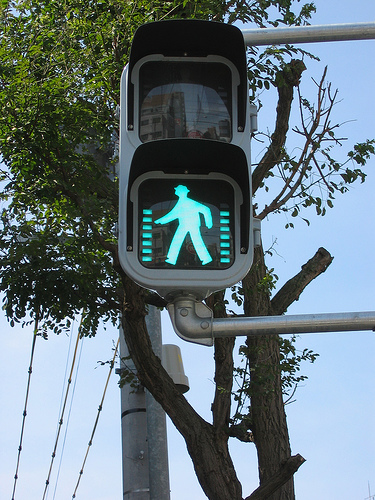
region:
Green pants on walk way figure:
[166, 231, 216, 274]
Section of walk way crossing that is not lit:
[125, 61, 247, 144]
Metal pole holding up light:
[179, 311, 367, 332]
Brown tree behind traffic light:
[142, 362, 304, 498]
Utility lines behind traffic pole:
[22, 357, 81, 480]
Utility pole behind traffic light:
[78, 324, 169, 498]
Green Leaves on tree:
[23, 184, 114, 316]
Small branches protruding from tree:
[276, 95, 371, 267]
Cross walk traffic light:
[90, 26, 273, 336]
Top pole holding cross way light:
[250, 19, 371, 63]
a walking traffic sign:
[124, 184, 232, 263]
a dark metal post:
[205, 318, 356, 341]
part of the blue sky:
[304, 378, 353, 473]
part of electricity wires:
[45, 363, 69, 433]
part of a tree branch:
[284, 87, 340, 202]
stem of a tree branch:
[262, 405, 287, 461]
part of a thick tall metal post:
[120, 417, 171, 494]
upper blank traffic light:
[150, 63, 215, 116]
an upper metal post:
[234, 20, 345, 47]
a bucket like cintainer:
[156, 339, 197, 393]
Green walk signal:
[113, 159, 273, 294]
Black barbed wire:
[26, 338, 165, 454]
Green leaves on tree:
[224, 321, 325, 441]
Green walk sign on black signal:
[97, 59, 303, 313]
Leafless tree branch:
[163, 384, 246, 479]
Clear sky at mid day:
[330, 355, 371, 447]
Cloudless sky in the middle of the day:
[321, 375, 372, 455]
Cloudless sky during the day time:
[318, 375, 372, 440]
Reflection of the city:
[120, 51, 262, 176]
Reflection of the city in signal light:
[129, 62, 262, 176]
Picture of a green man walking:
[155, 183, 217, 266]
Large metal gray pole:
[115, 285, 170, 498]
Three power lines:
[7, 250, 127, 498]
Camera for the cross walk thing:
[128, 52, 239, 145]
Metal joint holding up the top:
[168, 294, 374, 347]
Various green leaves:
[9, 114, 102, 206]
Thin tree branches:
[283, 78, 343, 215]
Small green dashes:
[220, 207, 232, 270]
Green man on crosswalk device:
[153, 183, 214, 264]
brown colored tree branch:
[235, 453, 306, 499]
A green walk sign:
[127, 181, 243, 272]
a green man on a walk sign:
[154, 179, 219, 267]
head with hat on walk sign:
[168, 181, 196, 201]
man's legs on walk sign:
[164, 227, 212, 266]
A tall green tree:
[2, 2, 337, 494]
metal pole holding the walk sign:
[240, 19, 373, 59]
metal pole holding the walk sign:
[175, 292, 374, 344]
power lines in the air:
[0, 308, 115, 497]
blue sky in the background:
[322, 345, 373, 498]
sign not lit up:
[130, 26, 248, 141]